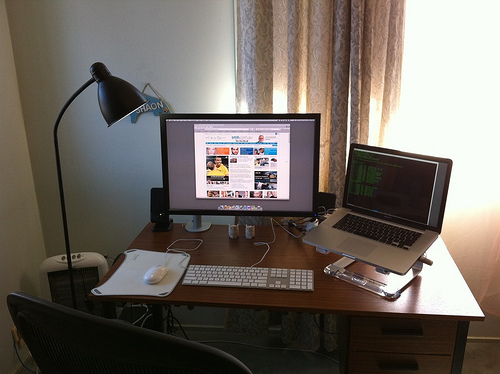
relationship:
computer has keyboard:
[159, 111, 322, 291] [184, 256, 315, 296]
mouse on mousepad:
[145, 262, 169, 284] [89, 236, 191, 297]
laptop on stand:
[299, 134, 449, 271] [317, 251, 437, 305]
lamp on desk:
[53, 64, 144, 307] [102, 217, 487, 371]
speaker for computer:
[148, 186, 173, 233] [335, 143, 458, 258]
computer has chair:
[159, 111, 322, 291] [2, 294, 234, 372]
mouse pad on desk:
[92, 247, 192, 296] [95, 222, 480, 319]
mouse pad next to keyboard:
[92, 247, 192, 296] [183, 262, 315, 292]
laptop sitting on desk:
[299, 134, 449, 271] [83, 187, 488, 369]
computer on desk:
[159, 111, 316, 291] [95, 222, 480, 319]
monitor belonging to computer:
[149, 90, 332, 224] [159, 111, 316, 291]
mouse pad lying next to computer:
[92, 247, 192, 296] [159, 111, 316, 291]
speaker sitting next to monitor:
[148, 186, 173, 233] [164, 116, 323, 213]